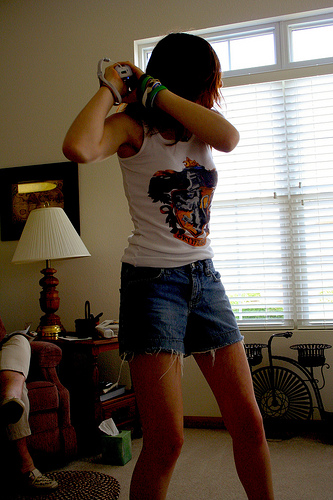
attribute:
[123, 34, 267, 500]
girl — playing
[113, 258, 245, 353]
shorts — jean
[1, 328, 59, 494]
legs — crossed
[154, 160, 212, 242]
design — colorful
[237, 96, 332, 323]
blinds — open, white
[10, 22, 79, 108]
wall — white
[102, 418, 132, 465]
tissue box — green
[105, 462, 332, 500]
floor — beige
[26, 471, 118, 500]
rug — beige, round, braided, multicolored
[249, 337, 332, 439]
decoration — metal, black, old fashioned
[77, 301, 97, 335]
basket — black, dark